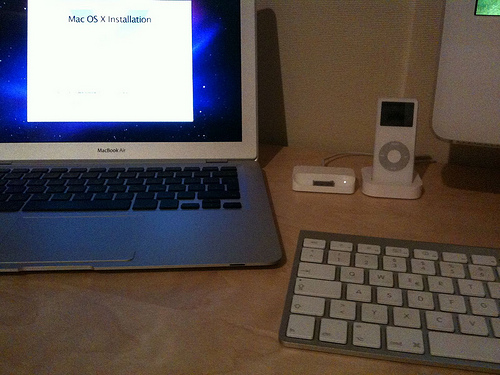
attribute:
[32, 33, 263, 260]
laptop — open, over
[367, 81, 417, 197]
ipod — sitting, charging, white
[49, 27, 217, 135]
memeo — displayed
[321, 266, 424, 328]
key — s, c, e, v, a, x, white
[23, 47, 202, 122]
screen — blue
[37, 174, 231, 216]
keys — black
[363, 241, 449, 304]
keys — white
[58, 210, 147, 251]
touchpad — gray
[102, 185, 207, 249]
surface — grey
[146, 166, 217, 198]
buttons — black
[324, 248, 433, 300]
buttons — white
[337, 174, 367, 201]
light — glowing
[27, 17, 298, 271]
computer — named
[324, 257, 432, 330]
letters — white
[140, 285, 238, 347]
desk — here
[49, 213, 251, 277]
macbook — gray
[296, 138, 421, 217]
device — charging